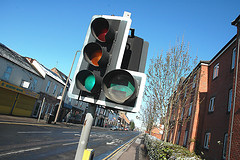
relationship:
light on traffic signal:
[72, 9, 158, 127] [67, 7, 150, 115]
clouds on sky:
[26, 40, 71, 68] [1, 1, 234, 82]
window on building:
[215, 65, 219, 78] [198, 11, 239, 157]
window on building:
[199, 131, 212, 151] [196, 36, 238, 156]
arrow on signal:
[107, 77, 134, 97] [64, 8, 158, 111]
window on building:
[209, 61, 220, 78] [149, 38, 230, 156]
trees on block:
[135, 35, 204, 144] [0, 114, 146, 160]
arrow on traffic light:
[107, 80, 134, 97] [61, 11, 147, 110]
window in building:
[211, 61, 221, 80] [189, 22, 237, 157]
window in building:
[230, 46, 239, 72] [189, 22, 237, 157]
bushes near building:
[143, 134, 201, 159] [156, 18, 239, 155]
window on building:
[192, 70, 196, 87] [166, 59, 208, 151]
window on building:
[200, 97, 215, 118] [178, 47, 239, 134]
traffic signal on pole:
[67, 7, 150, 115] [71, 102, 100, 158]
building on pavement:
[0, 78, 40, 116] [0, 115, 65, 128]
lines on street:
[0, 138, 77, 155] [0, 118, 145, 157]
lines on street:
[18, 130, 81, 133] [0, 118, 145, 157]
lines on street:
[101, 131, 143, 158] [0, 118, 145, 157]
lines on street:
[16, 130, 52, 134] [0, 118, 145, 157]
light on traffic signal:
[90, 19, 110, 43] [67, 7, 150, 115]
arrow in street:
[106, 134, 121, 146] [0, 126, 140, 156]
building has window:
[156, 18, 239, 155] [181, 130, 189, 145]